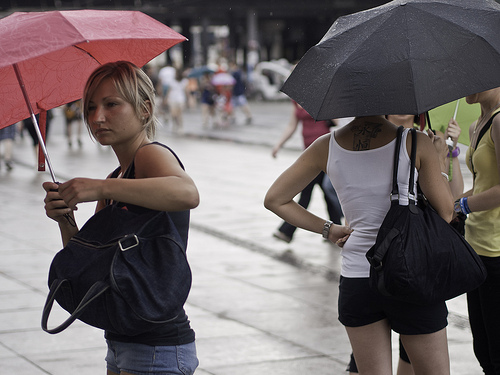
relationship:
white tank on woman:
[324, 130, 422, 280] [266, 110, 456, 372]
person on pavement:
[40, 59, 200, 372] [0, 138, 342, 373]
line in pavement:
[244, 293, 328, 374] [190, 200, 330, 369]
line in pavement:
[270, 285, 325, 315] [203, 232, 328, 374]